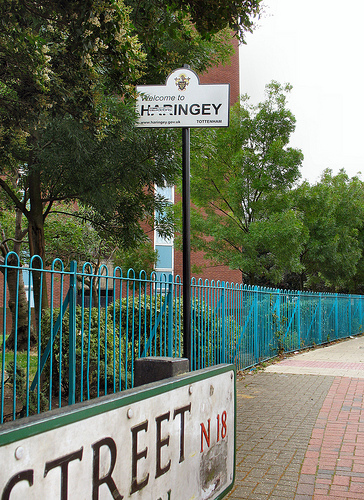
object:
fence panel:
[0, 249, 362, 424]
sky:
[241, 0, 363, 178]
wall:
[1, 1, 243, 349]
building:
[0, 1, 244, 355]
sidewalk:
[216, 334, 362, 499]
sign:
[134, 67, 230, 128]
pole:
[181, 127, 194, 369]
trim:
[134, 66, 231, 129]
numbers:
[216, 413, 221, 441]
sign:
[0, 362, 237, 500]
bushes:
[37, 305, 134, 402]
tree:
[0, 1, 148, 395]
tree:
[166, 78, 309, 285]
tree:
[300, 166, 363, 293]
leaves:
[275, 218, 288, 233]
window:
[153, 243, 174, 271]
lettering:
[200, 409, 228, 451]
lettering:
[140, 93, 222, 116]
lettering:
[1, 402, 193, 500]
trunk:
[25, 159, 64, 395]